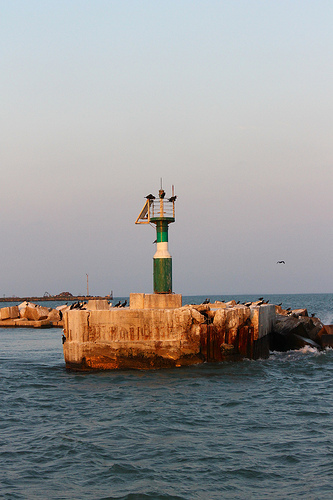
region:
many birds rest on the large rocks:
[190, 288, 313, 325]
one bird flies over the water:
[268, 243, 303, 268]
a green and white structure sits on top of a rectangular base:
[127, 161, 183, 316]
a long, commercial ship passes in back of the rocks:
[6, 259, 121, 302]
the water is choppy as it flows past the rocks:
[64, 333, 314, 478]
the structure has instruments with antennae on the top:
[129, 160, 193, 202]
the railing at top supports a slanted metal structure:
[125, 167, 184, 229]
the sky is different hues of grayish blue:
[217, 11, 312, 249]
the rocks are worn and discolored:
[85, 316, 252, 377]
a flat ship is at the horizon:
[3, 276, 145, 303]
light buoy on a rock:
[133, 181, 185, 308]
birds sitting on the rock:
[62, 280, 312, 324]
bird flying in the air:
[271, 253, 307, 276]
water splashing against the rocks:
[250, 325, 331, 371]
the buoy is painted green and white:
[137, 192, 184, 299]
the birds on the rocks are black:
[66, 297, 131, 312]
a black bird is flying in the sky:
[269, 255, 288, 267]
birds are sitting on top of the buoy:
[138, 182, 186, 219]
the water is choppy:
[15, 372, 304, 485]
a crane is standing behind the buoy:
[77, 266, 100, 298]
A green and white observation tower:
[133, 172, 181, 293]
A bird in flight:
[273, 256, 289, 266]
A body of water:
[1, 297, 331, 497]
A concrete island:
[58, 291, 329, 372]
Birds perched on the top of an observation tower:
[133, 170, 173, 232]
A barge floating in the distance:
[0, 269, 109, 298]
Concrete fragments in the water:
[0, 301, 61, 327]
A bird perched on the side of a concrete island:
[58, 333, 67, 346]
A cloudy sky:
[0, 1, 332, 294]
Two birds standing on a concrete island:
[113, 298, 131, 309]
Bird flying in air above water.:
[263, 253, 300, 275]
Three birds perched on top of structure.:
[141, 181, 187, 217]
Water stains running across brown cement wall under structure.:
[67, 321, 272, 373]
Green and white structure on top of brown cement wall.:
[150, 217, 176, 298]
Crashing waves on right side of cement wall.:
[269, 339, 331, 362]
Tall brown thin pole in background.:
[83, 265, 95, 302]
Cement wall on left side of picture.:
[4, 298, 71, 334]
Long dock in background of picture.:
[1, 296, 116, 300]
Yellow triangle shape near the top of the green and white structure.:
[132, 196, 153, 225]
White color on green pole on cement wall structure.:
[146, 242, 179, 258]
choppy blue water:
[79, 392, 213, 480]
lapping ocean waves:
[37, 390, 308, 487]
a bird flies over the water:
[246, 233, 326, 297]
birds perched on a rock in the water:
[193, 286, 331, 374]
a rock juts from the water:
[186, 285, 328, 379]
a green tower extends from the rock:
[130, 165, 191, 331]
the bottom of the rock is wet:
[34, 274, 201, 383]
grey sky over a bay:
[33, 162, 311, 398]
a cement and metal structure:
[118, 153, 211, 322]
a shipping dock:
[2, 258, 124, 306]